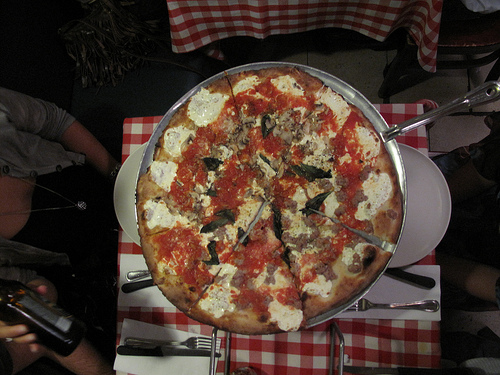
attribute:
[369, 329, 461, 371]
cloth — picnic-style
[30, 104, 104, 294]
person sitting — waiting to eat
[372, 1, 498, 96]
chair — wooden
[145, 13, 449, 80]
tablecloth — red, white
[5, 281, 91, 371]
bottle — beer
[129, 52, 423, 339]
pizza — sliced, baked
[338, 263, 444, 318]
napkin — white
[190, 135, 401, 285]
pizza — cooked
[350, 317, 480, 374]
clothes — red, white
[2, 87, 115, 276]
person — sitting, waiting to eat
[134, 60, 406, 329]
tray — silver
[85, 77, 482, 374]
table cloth — red, white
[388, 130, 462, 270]
plate — white, empty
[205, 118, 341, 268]
pizza — baked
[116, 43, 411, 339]
pizza — on a pan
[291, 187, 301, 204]
cheese — white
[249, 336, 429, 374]
cloth — red, white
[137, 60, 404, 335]
pan — metal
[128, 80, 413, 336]
pizza — baked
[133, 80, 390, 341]
pizza — whole, with cheese, sausage, and mushrooms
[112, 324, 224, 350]
utensil — silver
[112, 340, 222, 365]
utensil — silver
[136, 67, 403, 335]
pizza — cut, sliced, large, baked